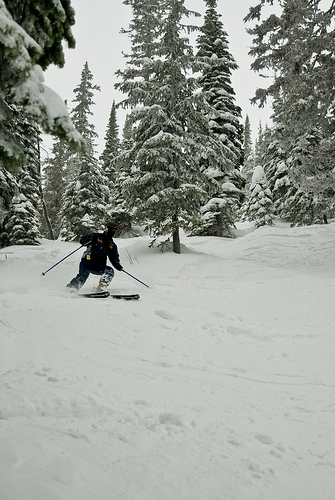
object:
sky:
[34, 0, 316, 149]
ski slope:
[1, 218, 334, 497]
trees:
[0, 0, 75, 249]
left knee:
[106, 266, 114, 277]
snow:
[0, 263, 335, 500]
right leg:
[67, 264, 90, 288]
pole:
[42, 242, 89, 276]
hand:
[80, 235, 91, 244]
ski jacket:
[79, 232, 123, 272]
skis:
[79, 291, 110, 298]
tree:
[115, 0, 220, 255]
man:
[66, 222, 123, 292]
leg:
[95, 265, 115, 288]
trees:
[260, 3, 324, 227]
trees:
[194, 1, 246, 235]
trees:
[62, 62, 104, 234]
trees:
[96, 95, 128, 244]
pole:
[116, 263, 150, 289]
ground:
[0, 291, 334, 498]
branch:
[192, 105, 228, 151]